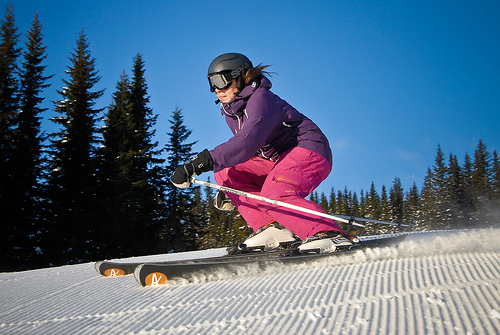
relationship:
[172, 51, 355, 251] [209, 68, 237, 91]
girl wearing goggles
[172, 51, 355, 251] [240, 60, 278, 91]
girl has hair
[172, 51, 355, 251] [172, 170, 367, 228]
girl holding pole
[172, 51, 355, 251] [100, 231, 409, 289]
girl on skis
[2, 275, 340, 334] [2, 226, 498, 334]
tracks in snow